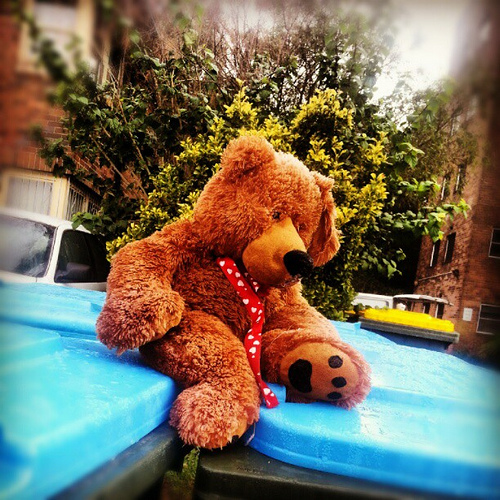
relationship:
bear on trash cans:
[95, 133, 372, 451] [2, 280, 496, 496]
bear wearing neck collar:
[96, 129, 373, 451] [216, 256, 281, 410]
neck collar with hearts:
[216, 256, 281, 410] [217, 259, 243, 288]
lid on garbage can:
[364, 307, 455, 333] [0, 280, 495, 496]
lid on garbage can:
[358, 302, 458, 332] [358, 307, 460, 352]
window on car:
[53, 226, 115, 284] [0, 206, 108, 293]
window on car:
[0, 213, 53, 278] [0, 206, 108, 293]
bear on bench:
[96, 129, 373, 451] [194, 320, 496, 498]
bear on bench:
[96, 129, 373, 451] [0, 280, 189, 498]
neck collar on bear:
[216, 256, 281, 410] [96, 129, 373, 451]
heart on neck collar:
[218, 254, 224, 264] [216, 256, 281, 410]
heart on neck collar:
[223, 262, 236, 275] [216, 256, 281, 410]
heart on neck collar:
[256, 387, 275, 402] [216, 256, 281, 410]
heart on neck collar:
[252, 333, 262, 351] [216, 256, 281, 410]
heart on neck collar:
[240, 330, 253, 340] [216, 256, 281, 410]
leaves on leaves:
[2, 0, 472, 319] [16, 0, 477, 324]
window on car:
[0, 215, 53, 277] [0, 202, 113, 289]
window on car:
[54, 229, 111, 283] [0, 202, 113, 289]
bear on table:
[95, 133, 372, 451] [246, 316, 498, 495]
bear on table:
[95, 133, 372, 451] [1, 279, 173, 498]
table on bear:
[246, 316, 498, 495] [95, 133, 372, 451]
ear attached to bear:
[219, 131, 275, 182] [96, 129, 373, 451]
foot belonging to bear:
[165, 380, 255, 451] [96, 129, 373, 451]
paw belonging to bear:
[93, 288, 186, 358] [96, 129, 373, 451]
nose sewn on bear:
[281, 248, 314, 277] [96, 129, 373, 451]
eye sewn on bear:
[270, 209, 283, 221] [96, 129, 373, 451]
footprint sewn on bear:
[286, 354, 347, 401] [96, 129, 373, 451]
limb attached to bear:
[94, 230, 185, 358] [95, 133, 372, 451]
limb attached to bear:
[135, 308, 260, 451] [95, 133, 372, 451]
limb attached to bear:
[257, 302, 372, 411] [95, 133, 372, 451]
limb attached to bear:
[272, 280, 339, 340] [95, 133, 372, 451]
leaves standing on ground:
[16, 0, 477, 324] [160, 440, 200, 498]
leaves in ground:
[16, 0, 477, 324] [4, 273, 496, 498]